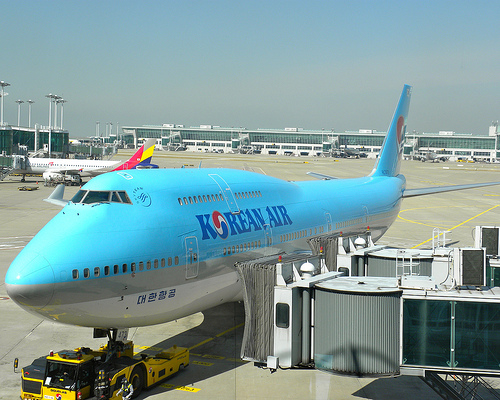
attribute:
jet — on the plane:
[2, 78, 496, 343]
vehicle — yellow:
[9, 335, 193, 399]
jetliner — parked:
[9, 67, 449, 319]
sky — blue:
[2, 3, 493, 138]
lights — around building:
[30, 81, 80, 136]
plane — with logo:
[48, 139, 465, 304]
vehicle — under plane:
[20, 312, 209, 399]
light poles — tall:
[0, 74, 84, 135]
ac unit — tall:
[454, 244, 491, 293]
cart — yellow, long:
[21, 333, 272, 397]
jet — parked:
[0, 143, 161, 180]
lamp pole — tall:
[43, 91, 57, 158]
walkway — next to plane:
[252, 235, 498, 372]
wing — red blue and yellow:
[98, 128, 173, 182]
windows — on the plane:
[67, 185, 130, 204]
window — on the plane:
[69, 189, 131, 206]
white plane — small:
[13, 148, 146, 180]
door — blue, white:
[177, 230, 204, 282]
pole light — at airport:
[37, 91, 56, 139]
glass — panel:
[403, 298, 451, 367]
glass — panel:
[455, 300, 498, 370]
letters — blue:
[138, 288, 177, 304]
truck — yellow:
[31, 303, 137, 397]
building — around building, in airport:
[117, 123, 499, 160]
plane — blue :
[106, 132, 381, 247]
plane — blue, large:
[1, 77, 491, 379]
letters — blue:
[189, 202, 303, 232]